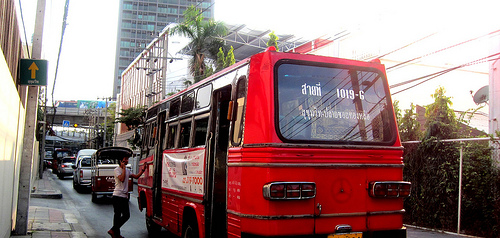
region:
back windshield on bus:
[274, 60, 396, 145]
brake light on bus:
[269, 183, 315, 197]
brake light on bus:
[371, 180, 411, 196]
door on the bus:
[210, 85, 231, 234]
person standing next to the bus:
[108, 145, 130, 237]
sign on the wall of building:
[17, 57, 50, 85]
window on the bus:
[193, 119, 204, 147]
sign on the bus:
[161, 148, 207, 194]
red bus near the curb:
[146, 51, 403, 236]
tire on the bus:
[181, 205, 201, 235]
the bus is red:
[83, 40, 415, 236]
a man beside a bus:
[76, 119, 216, 231]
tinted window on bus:
[191, 118, 208, 146]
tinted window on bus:
[176, 120, 191, 148]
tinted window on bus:
[163, 123, 177, 149]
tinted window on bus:
[196, 82, 211, 109]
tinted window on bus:
[181, 88, 195, 112]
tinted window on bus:
[170, 94, 182, 119]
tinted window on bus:
[147, 106, 162, 117]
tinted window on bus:
[278, 59, 396, 146]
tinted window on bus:
[233, 79, 249, 144]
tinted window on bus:
[149, 125, 158, 145]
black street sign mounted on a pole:
[16, 55, 51, 87]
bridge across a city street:
[36, 100, 115, 130]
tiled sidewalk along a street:
[30, 167, 84, 237]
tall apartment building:
[113, 0, 216, 99]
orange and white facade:
[116, 23, 173, 176]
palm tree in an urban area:
[168, 3, 226, 86]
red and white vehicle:
[91, 146, 132, 199]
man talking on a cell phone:
[108, 152, 148, 237]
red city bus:
[136, 45, 410, 236]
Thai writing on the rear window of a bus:
[298, 80, 373, 125]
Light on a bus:
[263, 174, 327, 208]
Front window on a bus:
[264, 52, 412, 158]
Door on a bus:
[206, 90, 245, 237]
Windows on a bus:
[161, 93, 226, 134]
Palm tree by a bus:
[167, 4, 256, 79]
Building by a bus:
[108, 50, 221, 151]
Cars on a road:
[56, 136, 143, 197]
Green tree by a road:
[403, 102, 475, 234]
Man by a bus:
[98, 155, 146, 235]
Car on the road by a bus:
[86, 146, 142, 200]